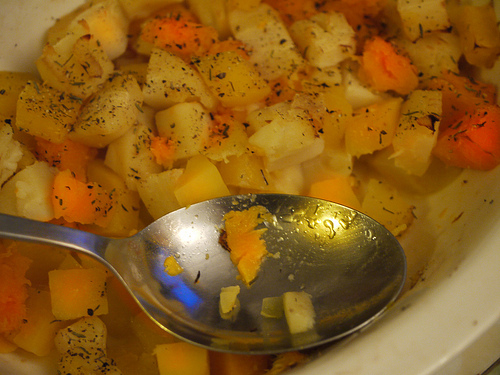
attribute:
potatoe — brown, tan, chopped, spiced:
[347, 98, 400, 160]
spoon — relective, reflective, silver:
[0, 191, 407, 355]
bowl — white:
[4, 1, 500, 374]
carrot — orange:
[439, 102, 499, 168]